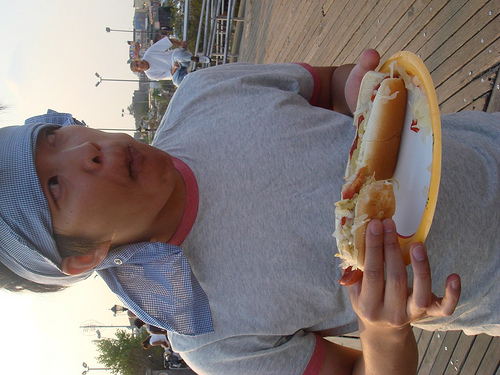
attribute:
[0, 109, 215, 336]
bandana — blue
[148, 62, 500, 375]
shirt — grey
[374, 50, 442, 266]
plate — yellow, round, paper, flat, white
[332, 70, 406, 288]
hot dogs — light brown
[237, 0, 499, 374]
deck — brown, wooden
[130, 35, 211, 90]
man — sitting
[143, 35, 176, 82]
shirt — white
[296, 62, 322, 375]
sleeves — red